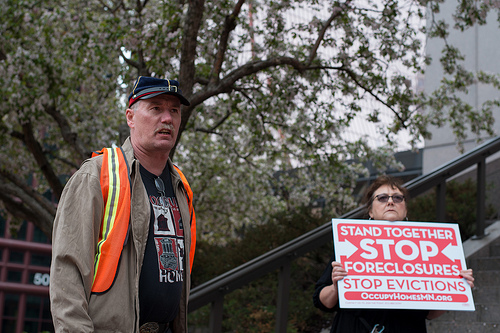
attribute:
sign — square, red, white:
[329, 221, 477, 312]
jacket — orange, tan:
[83, 150, 209, 291]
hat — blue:
[120, 76, 196, 104]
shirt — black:
[132, 162, 191, 328]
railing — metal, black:
[154, 98, 495, 332]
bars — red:
[5, 212, 66, 329]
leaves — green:
[48, 22, 104, 73]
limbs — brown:
[181, 6, 293, 81]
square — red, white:
[152, 200, 173, 239]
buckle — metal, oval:
[135, 321, 163, 332]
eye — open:
[148, 105, 164, 113]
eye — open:
[169, 107, 180, 116]